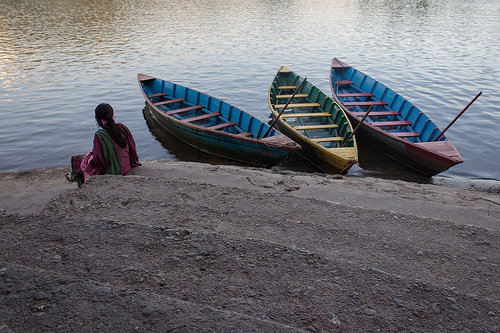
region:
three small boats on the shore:
[141, 55, 488, 205]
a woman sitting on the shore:
[61, 106, 191, 221]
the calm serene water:
[44, 16, 492, 63]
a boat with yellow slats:
[267, 49, 379, 201]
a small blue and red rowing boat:
[122, 63, 305, 180]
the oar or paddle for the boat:
[443, 72, 498, 172]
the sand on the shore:
[144, 153, 490, 255]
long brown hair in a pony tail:
[73, 82, 143, 169]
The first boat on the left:
[129, 58, 304, 198]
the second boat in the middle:
[256, 51, 376, 197]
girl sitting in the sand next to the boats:
[49, 92, 150, 196]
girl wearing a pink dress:
[59, 99, 166, 201]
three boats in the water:
[119, 42, 496, 184]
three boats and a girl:
[29, 23, 488, 238]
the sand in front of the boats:
[27, 160, 474, 320]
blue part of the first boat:
[139, 71, 266, 134]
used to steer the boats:
[249, 80, 491, 155]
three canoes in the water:
[128, 42, 470, 177]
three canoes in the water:
[143, 54, 485, 178]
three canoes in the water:
[146, 49, 481, 195]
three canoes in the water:
[127, 52, 472, 186]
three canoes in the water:
[148, 46, 460, 181]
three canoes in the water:
[133, 53, 471, 191]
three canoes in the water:
[138, 59, 477, 180]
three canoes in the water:
[123, 52, 458, 190]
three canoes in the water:
[127, 49, 464, 179]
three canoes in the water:
[131, 57, 491, 190]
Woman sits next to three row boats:
[25, 22, 490, 302]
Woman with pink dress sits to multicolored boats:
[32, 15, 492, 305]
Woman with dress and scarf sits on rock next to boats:
[32, 22, 488, 302]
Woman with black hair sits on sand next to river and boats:
[30, 30, 485, 270]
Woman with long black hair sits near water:
[0, 81, 140, 186]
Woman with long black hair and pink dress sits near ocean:
[0, 85, 140, 196]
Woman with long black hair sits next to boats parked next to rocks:
[35, 30, 490, 250]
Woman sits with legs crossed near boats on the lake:
[15, 15, 490, 292]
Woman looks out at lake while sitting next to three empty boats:
[16, 17, 492, 294]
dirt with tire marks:
[120, 183, 365, 304]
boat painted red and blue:
[322, 58, 445, 167]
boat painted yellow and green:
[275, 70, 353, 163]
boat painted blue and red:
[152, 84, 272, 160]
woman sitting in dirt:
[50, 102, 133, 179]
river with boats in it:
[137, 28, 458, 184]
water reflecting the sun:
[15, 0, 201, 56]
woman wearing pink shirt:
[88, 136, 143, 166]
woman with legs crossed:
[50, 153, 92, 188]